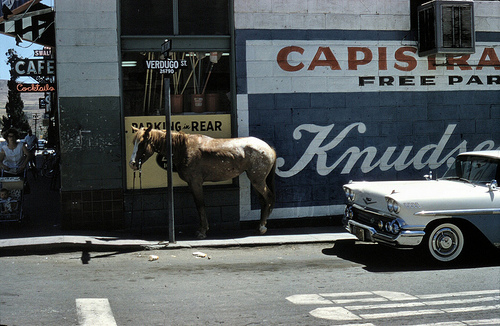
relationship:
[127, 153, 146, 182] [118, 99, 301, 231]
rein of horse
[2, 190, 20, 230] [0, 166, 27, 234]
child in stroller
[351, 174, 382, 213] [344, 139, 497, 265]
logo on car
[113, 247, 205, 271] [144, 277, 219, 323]
trash on road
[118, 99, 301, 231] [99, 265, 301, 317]
horse on street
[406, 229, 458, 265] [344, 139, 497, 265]
tire on car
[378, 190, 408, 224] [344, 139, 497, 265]
headlight of car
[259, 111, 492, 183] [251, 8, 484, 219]
letter on wall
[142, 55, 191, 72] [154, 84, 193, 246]
sign on pole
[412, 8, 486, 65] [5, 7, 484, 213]
air conditioner on building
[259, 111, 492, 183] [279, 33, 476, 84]
letter on wall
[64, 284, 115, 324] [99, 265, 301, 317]
"line on street